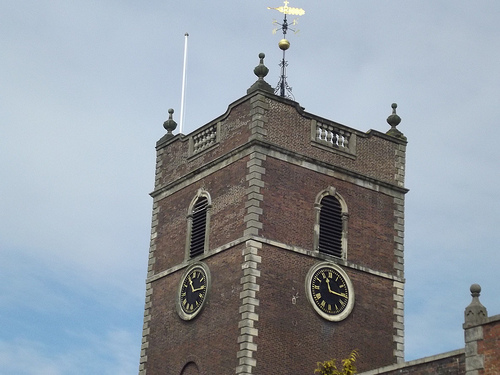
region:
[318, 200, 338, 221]
part of a wall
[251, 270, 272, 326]
edge of a wall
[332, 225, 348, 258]
part of a window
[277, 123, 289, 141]
top of a castle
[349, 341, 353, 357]
part of a plant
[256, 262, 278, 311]
edge of a wall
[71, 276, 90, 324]
part of the sky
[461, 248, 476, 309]
part of a pillar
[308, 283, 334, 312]
part of a clock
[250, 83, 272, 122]
tip of a castle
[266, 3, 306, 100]
metal weather vane on top of tower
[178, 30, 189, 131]
tall white lightning rod on tower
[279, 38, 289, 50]
round ball on weather vane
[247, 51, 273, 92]
finials on top of tower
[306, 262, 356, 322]
round clock on brick tower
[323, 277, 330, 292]
gold hour hand on clock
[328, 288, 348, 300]
gold minute hand on clock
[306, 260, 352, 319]
clock is black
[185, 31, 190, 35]
small black bulb on lightning rod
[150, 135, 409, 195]
narrow ledge around tower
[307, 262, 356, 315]
a black circle clock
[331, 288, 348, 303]
the minute hand of a clock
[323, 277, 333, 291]
the hour hand of a clock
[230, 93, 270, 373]
a light colored conner of a building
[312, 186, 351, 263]
an arched small window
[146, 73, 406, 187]
the top of a building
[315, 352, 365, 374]
green leafs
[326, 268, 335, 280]
the number 12 on a clock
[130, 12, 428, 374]
a tall brick building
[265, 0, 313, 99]
a weather vain on the roof of a building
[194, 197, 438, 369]
Clock on the tower.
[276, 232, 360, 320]
Hands on the clock.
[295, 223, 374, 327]
Numbers on the clock.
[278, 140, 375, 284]
Window on the tower.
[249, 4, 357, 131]
Spire on the tower.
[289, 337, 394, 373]
Tree by the building.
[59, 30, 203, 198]
Sky behind the tower.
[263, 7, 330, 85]
Weather vane on the tower.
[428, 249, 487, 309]
Knob on the building.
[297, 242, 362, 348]
Black face on the clock.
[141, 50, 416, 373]
two sides of brick clock tower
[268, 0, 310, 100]
weather vane above clock tower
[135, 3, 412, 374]
brick clock tower with stone corners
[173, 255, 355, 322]
outdoor clocks on brick tower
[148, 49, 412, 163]
top of clock tower with stone details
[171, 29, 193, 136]
lightning rod on top of tower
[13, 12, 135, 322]
overcast sky with clouds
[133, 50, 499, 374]
tower attached to building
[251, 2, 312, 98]
brass and black iron weather vane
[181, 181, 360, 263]
arched windows on tower